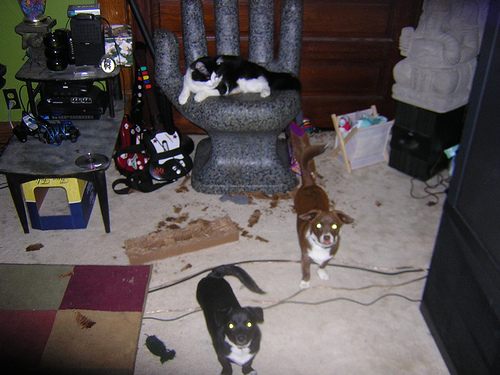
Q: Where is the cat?
A: On a chair.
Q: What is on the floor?
A: They are dogs.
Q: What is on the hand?
A: Cat.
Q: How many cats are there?
A: 1.